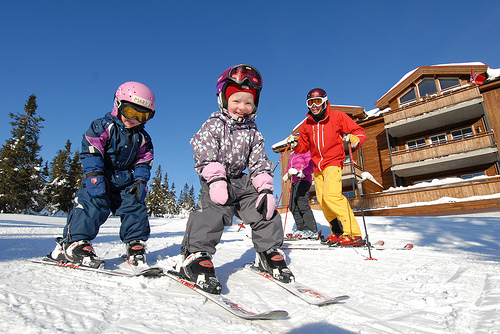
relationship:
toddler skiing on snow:
[175, 60, 295, 297] [423, 229, 495, 326]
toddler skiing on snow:
[41, 73, 166, 272] [423, 229, 495, 326]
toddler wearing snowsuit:
[52, 68, 167, 273] [67, 110, 155, 239]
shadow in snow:
[281, 319, 358, 333] [0, 210, 499, 331]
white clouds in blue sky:
[236, 19, 273, 44] [2, 0, 498, 183]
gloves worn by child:
[201, 159, 278, 221] [176, 65, 295, 292]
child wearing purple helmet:
[176, 65, 295, 292] [213, 64, 263, 121]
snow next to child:
[0, 210, 499, 331] [176, 65, 295, 292]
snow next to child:
[0, 210, 499, 331] [48, 81, 158, 273]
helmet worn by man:
[304, 86, 329, 103] [280, 81, 375, 249]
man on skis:
[280, 81, 375, 249] [279, 233, 415, 254]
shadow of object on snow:
[402, 214, 484, 254] [0, 210, 499, 331]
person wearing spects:
[294, 87, 366, 247] [302, 93, 332, 106]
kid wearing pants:
[183, 67, 295, 287] [185, 169, 280, 254]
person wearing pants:
[294, 87, 366, 247] [297, 147, 375, 247]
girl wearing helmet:
[52, 77, 157, 267] [105, 73, 159, 126]